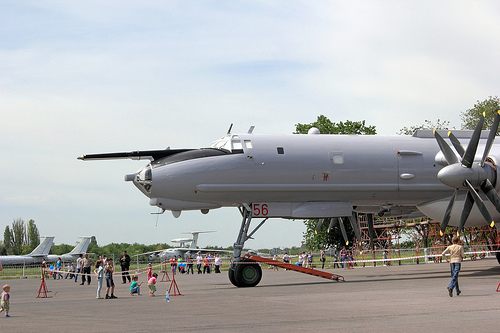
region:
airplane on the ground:
[85, 139, 499, 284]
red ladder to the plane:
[243, 259, 345, 290]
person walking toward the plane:
[451, 228, 473, 316]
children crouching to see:
[110, 265, 159, 310]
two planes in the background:
[0, 235, 102, 262]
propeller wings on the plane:
[417, 108, 498, 236]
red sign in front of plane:
[22, 261, 55, 308]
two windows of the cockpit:
[228, 134, 255, 151]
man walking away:
[67, 248, 83, 286]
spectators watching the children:
[163, 245, 352, 277]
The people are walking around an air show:
[0, 45, 496, 325]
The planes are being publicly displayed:
[10, 22, 491, 313]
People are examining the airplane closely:
[0, 23, 495, 315]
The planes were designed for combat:
[11, 21, 496, 306]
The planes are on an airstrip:
[1, 60, 497, 321]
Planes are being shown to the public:
[2, 57, 497, 319]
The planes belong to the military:
[2, 57, 492, 318]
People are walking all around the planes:
[0, 40, 498, 317]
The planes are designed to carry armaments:
[0, 75, 495, 307]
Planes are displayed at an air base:
[2, 50, 494, 324]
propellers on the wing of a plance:
[425, 122, 497, 229]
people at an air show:
[1, 232, 498, 303]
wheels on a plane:
[224, 256, 269, 286]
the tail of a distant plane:
[57, 235, 97, 266]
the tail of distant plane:
[8, 233, 59, 264]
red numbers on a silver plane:
[254, 201, 272, 219]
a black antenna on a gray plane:
[74, 146, 256, 168]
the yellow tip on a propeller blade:
[478, 109, 490, 123]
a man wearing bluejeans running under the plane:
[427, 221, 469, 302]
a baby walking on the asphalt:
[0, 282, 15, 320]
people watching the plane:
[16, 242, 175, 312]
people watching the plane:
[2, 215, 227, 324]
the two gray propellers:
[412, 131, 494, 236]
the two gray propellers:
[411, 80, 498, 285]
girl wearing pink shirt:
[144, 270, 159, 297]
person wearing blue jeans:
[441, 235, 466, 296]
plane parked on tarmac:
[78, 108, 497, 285]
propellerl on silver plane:
[435, 111, 497, 238]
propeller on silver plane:
[447, 113, 497, 232]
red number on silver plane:
[250, 201, 260, 215]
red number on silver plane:
[260, 204, 270, 218]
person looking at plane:
[105, 256, 117, 298]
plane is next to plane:
[0, 235, 57, 264]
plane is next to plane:
[48, 235, 93, 263]